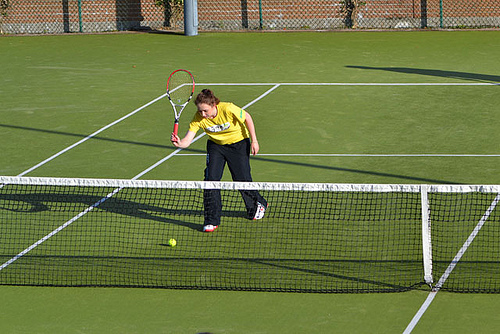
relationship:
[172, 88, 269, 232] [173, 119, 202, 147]
woman has arm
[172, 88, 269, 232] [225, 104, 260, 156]
woman has arm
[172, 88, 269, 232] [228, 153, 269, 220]
woman has leg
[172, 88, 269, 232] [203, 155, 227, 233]
woman has leg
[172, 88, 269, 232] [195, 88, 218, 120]
woman has head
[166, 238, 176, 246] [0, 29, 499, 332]
tennis ball on top of ground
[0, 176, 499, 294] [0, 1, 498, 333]
net divides tennis court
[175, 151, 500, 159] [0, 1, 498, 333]
line painted on tennis court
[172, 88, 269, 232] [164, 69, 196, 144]
woman holding tennis racket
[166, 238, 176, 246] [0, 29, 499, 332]
tennis ball lying on ground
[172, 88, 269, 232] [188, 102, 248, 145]
woman wearing shirt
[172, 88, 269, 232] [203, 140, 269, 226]
woman wearing pants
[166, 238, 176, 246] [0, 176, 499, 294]
tennis ball behind net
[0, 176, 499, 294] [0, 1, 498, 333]
net set up on tennis court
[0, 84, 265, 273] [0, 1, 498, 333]
line painted on tennis court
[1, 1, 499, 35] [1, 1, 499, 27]
wall behind fence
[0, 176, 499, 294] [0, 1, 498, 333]
net located on tennis court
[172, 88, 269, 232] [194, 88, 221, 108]
woman has hair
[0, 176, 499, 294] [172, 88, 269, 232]
net in front of woman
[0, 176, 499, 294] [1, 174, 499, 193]
net has trim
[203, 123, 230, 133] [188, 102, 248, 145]
logo printed on shirt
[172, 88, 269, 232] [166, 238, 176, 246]
woman bending for tennis ball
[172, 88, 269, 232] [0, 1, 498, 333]
woman standing on tennis court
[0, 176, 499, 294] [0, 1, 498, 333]
net on top of tennis court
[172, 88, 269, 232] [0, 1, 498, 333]
woman playing on tennis court